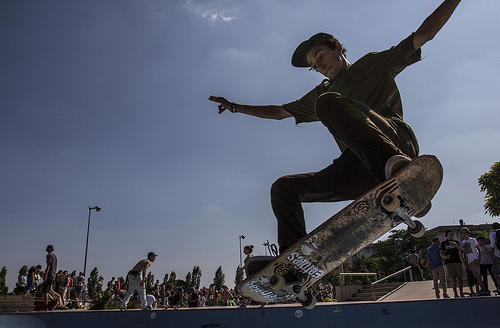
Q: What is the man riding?
A: Skateboard.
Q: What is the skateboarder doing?
A: Jumping in air.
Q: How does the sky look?
A: Clear and blue.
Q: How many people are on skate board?
A: 1.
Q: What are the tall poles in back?
A: Lights.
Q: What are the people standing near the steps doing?
A: Watching the skateboarder.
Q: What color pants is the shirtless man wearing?
A: White.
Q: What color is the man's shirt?
A: Black.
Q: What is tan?
A: Skateboard.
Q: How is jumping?
A: The boy.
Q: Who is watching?
A: Crowd.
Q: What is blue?
A: Sky.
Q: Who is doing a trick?
A: Boy.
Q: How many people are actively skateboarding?
A: Two.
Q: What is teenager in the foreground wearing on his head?
A: Hat.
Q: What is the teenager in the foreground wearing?
A: Jeans and a t-shirt.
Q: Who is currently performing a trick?
A: The teenage boy in the foreground.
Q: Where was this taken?
A: At a skate park.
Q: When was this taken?
A: During the day.